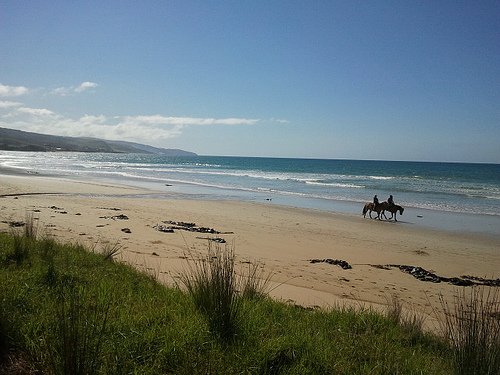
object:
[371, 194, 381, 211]
person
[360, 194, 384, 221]
horse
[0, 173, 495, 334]
beach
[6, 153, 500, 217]
ocean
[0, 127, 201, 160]
hill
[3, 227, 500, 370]
area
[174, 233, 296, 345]
grass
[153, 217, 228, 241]
rock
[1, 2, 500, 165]
sky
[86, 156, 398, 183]
waves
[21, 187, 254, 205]
stream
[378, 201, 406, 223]
horse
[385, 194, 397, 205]
person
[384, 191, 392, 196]
head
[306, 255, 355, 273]
seaweed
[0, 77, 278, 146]
cloud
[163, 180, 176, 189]
debris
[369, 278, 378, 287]
footprint